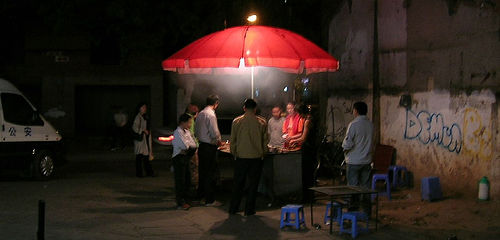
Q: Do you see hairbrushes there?
A: No, there are no hairbrushes.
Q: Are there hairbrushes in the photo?
A: No, there are no hairbrushes.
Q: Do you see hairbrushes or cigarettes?
A: No, there are no hairbrushes or cigarettes.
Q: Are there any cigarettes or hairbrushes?
A: No, there are no hairbrushes or cigarettes.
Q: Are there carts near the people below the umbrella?
A: Yes, there is a cart near the people.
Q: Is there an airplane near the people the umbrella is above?
A: No, there is a cart near the people.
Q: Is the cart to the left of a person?
A: No, the cart is to the right of a person.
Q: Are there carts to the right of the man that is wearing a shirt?
A: Yes, there is a cart to the right of the man.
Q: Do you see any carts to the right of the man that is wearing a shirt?
A: Yes, there is a cart to the right of the man.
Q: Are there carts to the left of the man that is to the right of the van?
A: No, the cart is to the right of the man.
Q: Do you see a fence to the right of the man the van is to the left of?
A: No, there is a cart to the right of the man.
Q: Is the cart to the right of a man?
A: Yes, the cart is to the right of a man.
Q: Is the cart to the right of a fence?
A: No, the cart is to the right of a man.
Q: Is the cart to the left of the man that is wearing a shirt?
A: No, the cart is to the right of the man.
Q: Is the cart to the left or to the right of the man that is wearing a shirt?
A: The cart is to the right of the man.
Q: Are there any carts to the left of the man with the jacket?
A: Yes, there is a cart to the left of the man.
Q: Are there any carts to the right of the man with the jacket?
A: No, the cart is to the left of the man.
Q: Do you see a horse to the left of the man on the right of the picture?
A: No, there is a cart to the left of the man.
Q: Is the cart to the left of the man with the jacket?
A: Yes, the cart is to the left of the man.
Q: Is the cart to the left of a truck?
A: No, the cart is to the left of the man.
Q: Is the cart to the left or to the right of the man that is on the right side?
A: The cart is to the left of the man.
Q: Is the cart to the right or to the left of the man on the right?
A: The cart is to the left of the man.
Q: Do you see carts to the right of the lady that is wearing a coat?
A: Yes, there is a cart to the right of the lady.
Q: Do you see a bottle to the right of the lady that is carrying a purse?
A: No, there is a cart to the right of the lady.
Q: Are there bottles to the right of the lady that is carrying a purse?
A: No, there is a cart to the right of the lady.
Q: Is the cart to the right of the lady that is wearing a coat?
A: Yes, the cart is to the right of the lady.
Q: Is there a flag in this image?
A: No, there are no flags.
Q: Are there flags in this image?
A: No, there are no flags.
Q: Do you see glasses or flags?
A: No, there are no flags or glasses.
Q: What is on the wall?
A: The graffiti is on the wall.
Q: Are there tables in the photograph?
A: Yes, there is a table.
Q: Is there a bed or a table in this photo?
A: Yes, there is a table.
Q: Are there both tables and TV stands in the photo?
A: No, there is a table but no TV stands.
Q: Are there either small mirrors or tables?
A: Yes, there is a small table.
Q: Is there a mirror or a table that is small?
A: Yes, the table is small.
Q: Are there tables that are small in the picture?
A: Yes, there is a small table.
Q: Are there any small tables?
A: Yes, there is a small table.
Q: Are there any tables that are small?
A: Yes, there is a table that is small.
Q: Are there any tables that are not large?
A: Yes, there is a small table.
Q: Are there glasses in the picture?
A: No, there are no glasses.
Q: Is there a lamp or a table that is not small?
A: No, there is a table but it is small.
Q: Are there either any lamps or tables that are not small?
A: No, there is a table but it is small.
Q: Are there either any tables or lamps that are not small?
A: No, there is a table but it is small.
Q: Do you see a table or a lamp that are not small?
A: No, there is a table but it is small.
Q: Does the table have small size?
A: Yes, the table is small.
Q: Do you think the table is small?
A: Yes, the table is small.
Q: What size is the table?
A: The table is small.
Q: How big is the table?
A: The table is small.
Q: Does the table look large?
A: No, the table is small.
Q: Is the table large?
A: No, the table is small.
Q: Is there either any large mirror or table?
A: No, there is a table but it is small.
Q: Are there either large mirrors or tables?
A: No, there is a table but it is small.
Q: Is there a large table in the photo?
A: No, there is a table but it is small.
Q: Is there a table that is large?
A: No, there is a table but it is small.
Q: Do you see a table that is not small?
A: No, there is a table but it is small.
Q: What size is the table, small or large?
A: The table is small.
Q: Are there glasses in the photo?
A: No, there are no glasses.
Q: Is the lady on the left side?
A: Yes, the lady is on the left of the image.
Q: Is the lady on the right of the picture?
A: No, the lady is on the left of the image.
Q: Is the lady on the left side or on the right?
A: The lady is on the left of the image.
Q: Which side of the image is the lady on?
A: The lady is on the left of the image.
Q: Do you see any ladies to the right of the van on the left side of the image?
A: Yes, there is a lady to the right of the van.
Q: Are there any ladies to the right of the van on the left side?
A: Yes, there is a lady to the right of the van.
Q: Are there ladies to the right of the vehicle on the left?
A: Yes, there is a lady to the right of the van.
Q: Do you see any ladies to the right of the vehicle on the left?
A: Yes, there is a lady to the right of the van.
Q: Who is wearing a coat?
A: The lady is wearing a coat.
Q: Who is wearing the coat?
A: The lady is wearing a coat.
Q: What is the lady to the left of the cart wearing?
A: The lady is wearing a coat.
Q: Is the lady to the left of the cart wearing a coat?
A: Yes, the lady is wearing a coat.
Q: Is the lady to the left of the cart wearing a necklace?
A: No, the lady is wearing a coat.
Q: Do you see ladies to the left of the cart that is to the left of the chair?
A: Yes, there is a lady to the left of the cart.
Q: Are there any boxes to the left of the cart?
A: No, there is a lady to the left of the cart.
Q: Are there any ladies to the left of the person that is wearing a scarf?
A: Yes, there is a lady to the left of the person.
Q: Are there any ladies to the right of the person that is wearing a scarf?
A: No, the lady is to the left of the person.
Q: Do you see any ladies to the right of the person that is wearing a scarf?
A: No, the lady is to the left of the person.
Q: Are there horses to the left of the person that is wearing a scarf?
A: No, there is a lady to the left of the person.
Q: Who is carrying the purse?
A: The lady is carrying the purse.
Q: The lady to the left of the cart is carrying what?
A: The lady is carrying a purse.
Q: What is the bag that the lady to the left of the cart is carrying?
A: The bag is a purse.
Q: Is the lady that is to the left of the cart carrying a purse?
A: Yes, the lady is carrying a purse.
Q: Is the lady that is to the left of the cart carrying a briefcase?
A: No, the lady is carrying a purse.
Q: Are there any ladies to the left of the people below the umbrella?
A: Yes, there is a lady to the left of the people.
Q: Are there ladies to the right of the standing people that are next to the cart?
A: No, the lady is to the left of the people.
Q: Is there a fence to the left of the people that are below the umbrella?
A: No, there is a lady to the left of the people.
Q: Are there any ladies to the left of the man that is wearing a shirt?
A: Yes, there is a lady to the left of the man.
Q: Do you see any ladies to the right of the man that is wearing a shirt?
A: No, the lady is to the left of the man.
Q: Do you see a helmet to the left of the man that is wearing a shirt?
A: No, there is a lady to the left of the man.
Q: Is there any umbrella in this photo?
A: Yes, there is an umbrella.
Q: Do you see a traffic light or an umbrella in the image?
A: Yes, there is an umbrella.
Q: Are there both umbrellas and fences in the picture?
A: No, there is an umbrella but no fences.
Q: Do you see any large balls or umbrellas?
A: Yes, there is a large umbrella.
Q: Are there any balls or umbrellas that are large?
A: Yes, the umbrella is large.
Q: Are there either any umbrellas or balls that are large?
A: Yes, the umbrella is large.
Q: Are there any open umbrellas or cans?
A: Yes, there is an open umbrella.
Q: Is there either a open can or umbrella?
A: Yes, there is an open umbrella.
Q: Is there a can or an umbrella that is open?
A: Yes, the umbrella is open.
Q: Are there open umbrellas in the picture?
A: Yes, there is an open umbrella.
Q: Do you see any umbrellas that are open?
A: Yes, there is an open umbrella.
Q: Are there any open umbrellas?
A: Yes, there is an open umbrella.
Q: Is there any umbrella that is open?
A: Yes, there is an umbrella that is open.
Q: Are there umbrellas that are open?
A: Yes, there is an umbrella that is open.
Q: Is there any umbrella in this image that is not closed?
A: Yes, there is a open umbrella.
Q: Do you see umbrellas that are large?
A: Yes, there is a large umbrella.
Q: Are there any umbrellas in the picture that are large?
A: Yes, there is an umbrella that is large.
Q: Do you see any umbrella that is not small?
A: Yes, there is a large umbrella.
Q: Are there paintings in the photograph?
A: No, there are no paintings.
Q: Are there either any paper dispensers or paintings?
A: No, there are no paintings or paper dispensers.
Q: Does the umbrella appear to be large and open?
A: Yes, the umbrella is large and open.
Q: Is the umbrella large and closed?
A: No, the umbrella is large but open.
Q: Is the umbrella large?
A: Yes, the umbrella is large.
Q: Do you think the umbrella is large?
A: Yes, the umbrella is large.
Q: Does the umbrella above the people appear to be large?
A: Yes, the umbrella is large.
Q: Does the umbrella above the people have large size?
A: Yes, the umbrella is large.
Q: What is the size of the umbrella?
A: The umbrella is large.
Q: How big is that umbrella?
A: The umbrella is large.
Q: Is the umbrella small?
A: No, the umbrella is large.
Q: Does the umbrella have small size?
A: No, the umbrella is large.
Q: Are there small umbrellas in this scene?
A: No, there is an umbrella but it is large.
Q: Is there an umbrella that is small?
A: No, there is an umbrella but it is large.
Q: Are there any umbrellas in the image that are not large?
A: No, there is an umbrella but it is large.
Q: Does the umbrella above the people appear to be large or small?
A: The umbrella is large.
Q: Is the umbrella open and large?
A: Yes, the umbrella is open and large.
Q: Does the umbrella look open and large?
A: Yes, the umbrella is open and large.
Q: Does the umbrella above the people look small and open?
A: No, the umbrella is open but large.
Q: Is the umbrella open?
A: Yes, the umbrella is open.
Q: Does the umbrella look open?
A: Yes, the umbrella is open.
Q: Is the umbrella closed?
A: No, the umbrella is open.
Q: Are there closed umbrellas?
A: No, there is an umbrella but it is open.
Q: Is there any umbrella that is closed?
A: No, there is an umbrella but it is open.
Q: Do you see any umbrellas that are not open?
A: No, there is an umbrella but it is open.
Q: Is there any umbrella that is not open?
A: No, there is an umbrella but it is open.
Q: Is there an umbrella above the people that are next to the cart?
A: Yes, there is an umbrella above the people.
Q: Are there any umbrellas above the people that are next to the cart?
A: Yes, there is an umbrella above the people.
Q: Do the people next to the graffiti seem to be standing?
A: Yes, the people are standing.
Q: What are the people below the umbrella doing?
A: The people are standing.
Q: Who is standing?
A: The people are standing.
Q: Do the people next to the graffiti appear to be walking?
A: No, the people are standing.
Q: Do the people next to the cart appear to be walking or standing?
A: The people are standing.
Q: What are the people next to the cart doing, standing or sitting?
A: The people are standing.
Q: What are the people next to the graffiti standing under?
A: The people are standing under the umbrella.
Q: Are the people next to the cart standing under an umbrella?
A: Yes, the people are standing under an umbrella.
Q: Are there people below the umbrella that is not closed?
A: Yes, there are people below the umbrella.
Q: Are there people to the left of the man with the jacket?
A: Yes, there are people to the left of the man.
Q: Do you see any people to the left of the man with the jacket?
A: Yes, there are people to the left of the man.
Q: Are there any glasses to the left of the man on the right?
A: No, there are people to the left of the man.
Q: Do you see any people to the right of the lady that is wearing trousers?
A: Yes, there are people to the right of the lady.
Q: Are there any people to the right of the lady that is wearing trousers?
A: Yes, there are people to the right of the lady.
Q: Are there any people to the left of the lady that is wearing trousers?
A: No, the people are to the right of the lady.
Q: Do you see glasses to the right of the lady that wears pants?
A: No, there are people to the right of the lady.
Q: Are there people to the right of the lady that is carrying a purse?
A: Yes, there are people to the right of the lady.